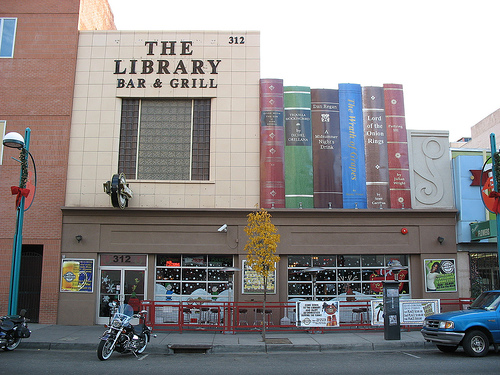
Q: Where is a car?
A: On a street.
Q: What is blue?
A: Car.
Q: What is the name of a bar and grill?
A: "THE LIBRARY".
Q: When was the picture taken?
A: Daytime.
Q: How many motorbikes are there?
A: One.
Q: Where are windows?
A: On a building.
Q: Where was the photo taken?
A: In a city.